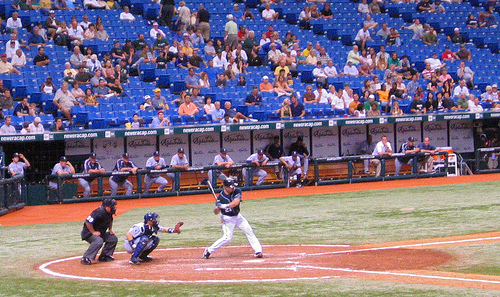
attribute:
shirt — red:
[440, 49, 455, 62]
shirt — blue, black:
[213, 187, 243, 216]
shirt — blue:
[215, 185, 245, 217]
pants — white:
[209, 211, 261, 255]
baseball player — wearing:
[201, 165, 284, 269]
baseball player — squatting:
[119, 209, 186, 271]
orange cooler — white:
[438, 145, 451, 160]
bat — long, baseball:
[202, 176, 224, 206]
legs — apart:
[206, 214, 267, 257]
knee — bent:
[215, 228, 234, 242]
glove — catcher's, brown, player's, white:
[173, 219, 189, 237]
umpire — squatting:
[63, 198, 120, 263]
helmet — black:
[219, 176, 239, 189]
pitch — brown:
[319, 249, 453, 273]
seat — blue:
[158, 74, 173, 86]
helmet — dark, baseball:
[222, 177, 236, 188]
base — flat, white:
[240, 253, 271, 269]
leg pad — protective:
[145, 238, 161, 259]